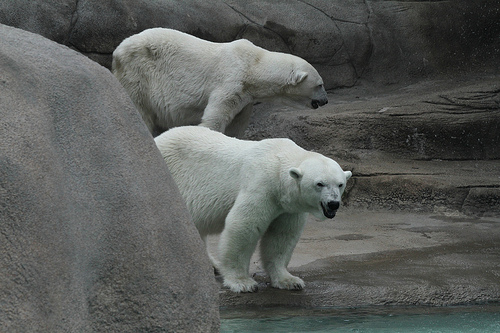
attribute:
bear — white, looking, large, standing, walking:
[158, 116, 369, 296]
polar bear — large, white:
[106, 13, 365, 144]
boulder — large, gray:
[1, 21, 234, 332]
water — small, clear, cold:
[225, 301, 460, 330]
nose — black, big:
[327, 197, 344, 215]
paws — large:
[223, 263, 322, 303]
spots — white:
[397, 122, 452, 178]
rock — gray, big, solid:
[367, 72, 483, 240]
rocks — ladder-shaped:
[139, 214, 453, 292]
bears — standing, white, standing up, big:
[99, 13, 358, 310]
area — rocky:
[1, 1, 493, 324]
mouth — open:
[321, 200, 340, 225]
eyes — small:
[314, 176, 346, 193]